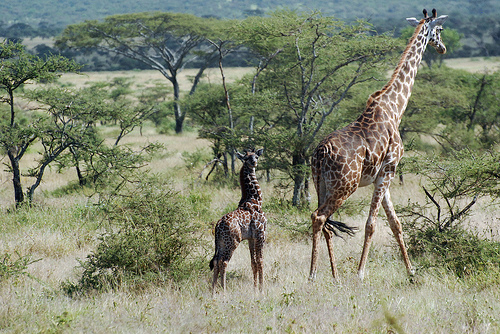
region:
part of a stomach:
[359, 133, 381, 170]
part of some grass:
[313, 299, 345, 329]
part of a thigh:
[225, 238, 237, 263]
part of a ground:
[301, 296, 334, 323]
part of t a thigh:
[317, 151, 354, 207]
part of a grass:
[281, 294, 298, 325]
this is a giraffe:
[309, 0, 466, 270]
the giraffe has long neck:
[378, 15, 450, 109]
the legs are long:
[301, 185, 416, 270]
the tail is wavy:
[329, 219, 351, 238]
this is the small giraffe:
[206, 148, 275, 285]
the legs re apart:
[354, 205, 407, 270]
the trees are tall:
[248, 25, 335, 104]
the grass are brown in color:
[291, 292, 338, 327]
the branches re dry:
[156, 52, 184, 78]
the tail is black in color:
[323, 220, 348, 241]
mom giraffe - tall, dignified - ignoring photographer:
[298, 3, 462, 293]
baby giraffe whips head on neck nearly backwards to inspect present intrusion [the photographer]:
[204, 146, 274, 308]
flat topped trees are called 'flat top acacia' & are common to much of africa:
[25, 8, 449, 191]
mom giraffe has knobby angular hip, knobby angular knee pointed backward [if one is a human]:
[300, 157, 361, 232]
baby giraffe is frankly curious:
[229, 146, 269, 213]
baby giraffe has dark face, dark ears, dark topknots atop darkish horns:
[229, 144, 265, 170]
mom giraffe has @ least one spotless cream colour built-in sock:
[350, 265, 367, 280]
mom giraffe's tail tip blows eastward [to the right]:
[312, 210, 362, 241]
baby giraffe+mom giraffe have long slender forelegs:
[240, 141, 431, 309]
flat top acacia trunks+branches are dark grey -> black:
[80, 28, 370, 153]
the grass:
[283, 257, 368, 293]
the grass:
[323, 279, 353, 304]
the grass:
[329, 299, 348, 323]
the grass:
[314, 299, 336, 325]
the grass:
[302, 267, 345, 327]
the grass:
[330, 262, 359, 324]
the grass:
[259, 247, 344, 332]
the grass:
[297, 328, 339, 333]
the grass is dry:
[302, 268, 360, 315]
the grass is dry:
[280, 281, 328, 318]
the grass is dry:
[270, 301, 324, 331]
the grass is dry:
[263, 281, 344, 329]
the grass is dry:
[317, 280, 357, 322]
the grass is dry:
[273, 245, 380, 313]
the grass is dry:
[343, 282, 378, 307]